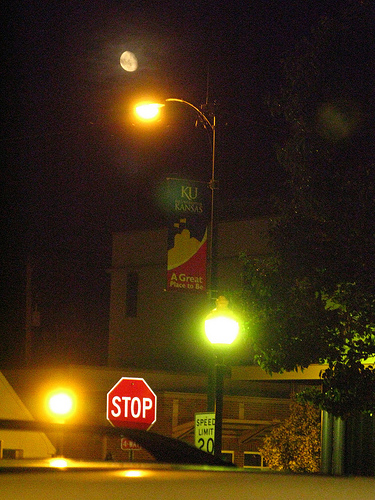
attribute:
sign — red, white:
[104, 374, 159, 432]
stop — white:
[113, 396, 152, 419]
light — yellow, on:
[122, 93, 173, 133]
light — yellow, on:
[34, 375, 96, 431]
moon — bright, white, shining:
[118, 45, 146, 75]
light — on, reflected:
[184, 289, 260, 361]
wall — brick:
[116, 388, 291, 469]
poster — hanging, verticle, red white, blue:
[161, 177, 211, 293]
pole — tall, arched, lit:
[130, 92, 221, 307]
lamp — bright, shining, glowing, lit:
[196, 294, 246, 456]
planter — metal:
[317, 391, 371, 478]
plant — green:
[309, 361, 374, 411]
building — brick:
[103, 220, 287, 372]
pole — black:
[212, 361, 226, 456]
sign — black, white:
[196, 415, 215, 454]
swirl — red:
[158, 237, 210, 290]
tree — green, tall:
[243, 7, 373, 370]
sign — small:
[121, 436, 140, 452]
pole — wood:
[19, 216, 42, 378]